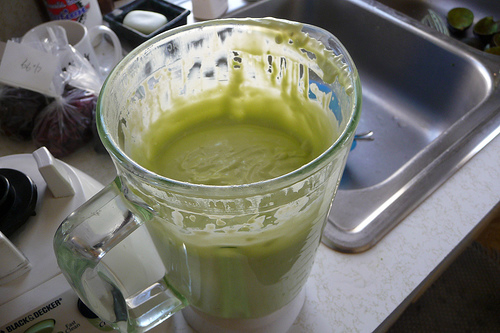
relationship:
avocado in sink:
[435, 4, 496, 61] [315, 4, 497, 234]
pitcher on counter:
[52, 15, 363, 331] [0, 0, 498, 331]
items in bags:
[67, 86, 97, 145] [2, 26, 99, 145]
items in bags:
[2, 86, 49, 144] [2, 26, 99, 145]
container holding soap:
[106, 5, 202, 51] [117, 5, 172, 37]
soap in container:
[117, 5, 172, 37] [106, 5, 202, 51]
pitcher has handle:
[52, 15, 363, 331] [50, 175, 185, 331]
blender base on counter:
[1, 146, 142, 331] [0, 0, 498, 331]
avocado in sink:
[435, 4, 496, 61] [172, 0, 484, 263]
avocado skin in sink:
[440, 1, 476, 41] [172, 0, 484, 263]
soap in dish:
[117, 5, 172, 37] [100, 0, 194, 49]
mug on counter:
[11, 4, 68, 56] [0, 0, 498, 331]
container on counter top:
[106, 5, 202, 51] [0, 1, 480, 330]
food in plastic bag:
[4, 85, 97, 157] [15, 37, 107, 160]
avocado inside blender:
[200, 126, 282, 162] [49, 12, 366, 328]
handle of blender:
[50, 175, 185, 331] [49, 12, 366, 328]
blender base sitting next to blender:
[1, 146, 142, 331] [49, 12, 366, 328]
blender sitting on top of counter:
[49, 12, 366, 328] [0, 0, 498, 331]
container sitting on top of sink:
[106, 5, 202, 51] [117, 0, 484, 254]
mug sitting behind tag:
[11, 4, 68, 56] [1, 38, 61, 98]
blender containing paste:
[49, 12, 366, 328] [205, 117, 249, 156]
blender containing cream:
[49, 12, 366, 328] [151, 114, 382, 244]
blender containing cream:
[86, 176, 336, 321] [176, 122, 271, 174]